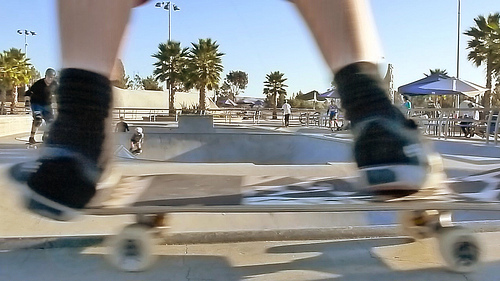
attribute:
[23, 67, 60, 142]
man — skateboarding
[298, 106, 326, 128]
bicycle — parked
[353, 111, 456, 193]
shoe — white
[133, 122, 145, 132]
helmet — white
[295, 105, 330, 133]
bicycle — pictured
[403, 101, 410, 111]
shirt — teal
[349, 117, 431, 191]
shoes — black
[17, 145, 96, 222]
shoes — black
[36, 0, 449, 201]
legs — apart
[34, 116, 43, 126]
knee — bent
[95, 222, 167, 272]
wheel — white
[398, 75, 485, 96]
canopies — blue